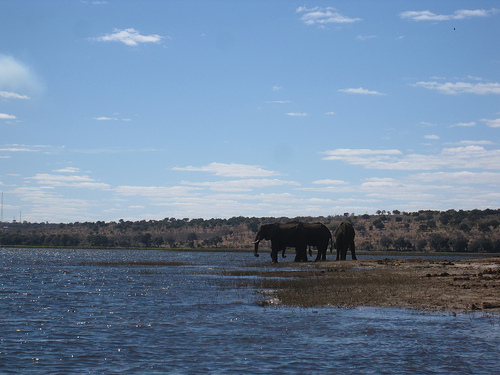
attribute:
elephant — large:
[275, 214, 335, 268]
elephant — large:
[255, 219, 314, 267]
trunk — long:
[249, 237, 261, 262]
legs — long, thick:
[265, 243, 281, 269]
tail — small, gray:
[303, 238, 316, 258]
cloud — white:
[338, 85, 383, 98]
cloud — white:
[91, 21, 165, 51]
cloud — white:
[89, 116, 131, 123]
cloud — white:
[294, 1, 358, 30]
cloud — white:
[418, 73, 498, 97]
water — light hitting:
[57, 254, 193, 357]